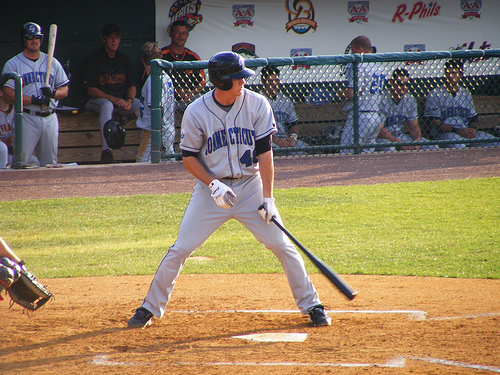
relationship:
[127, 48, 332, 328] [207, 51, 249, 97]
man has head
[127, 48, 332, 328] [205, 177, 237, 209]
man has hand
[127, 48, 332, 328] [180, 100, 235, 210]
man has arm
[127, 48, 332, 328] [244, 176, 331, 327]
man has leg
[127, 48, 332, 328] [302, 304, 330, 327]
man has foot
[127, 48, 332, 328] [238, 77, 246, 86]
man has nose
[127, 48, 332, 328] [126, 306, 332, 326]
man wearing shoes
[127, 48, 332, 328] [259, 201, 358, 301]
man holding bat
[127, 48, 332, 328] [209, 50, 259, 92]
man wearing hat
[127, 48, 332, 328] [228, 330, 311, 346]
man standing near home plate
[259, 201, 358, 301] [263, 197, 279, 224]
bat in left hand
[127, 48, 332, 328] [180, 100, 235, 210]
batter has right arm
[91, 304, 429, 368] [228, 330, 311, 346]
chalk box around home plate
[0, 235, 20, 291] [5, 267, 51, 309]
catcher has glove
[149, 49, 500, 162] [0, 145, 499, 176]
chain link fence at edge of field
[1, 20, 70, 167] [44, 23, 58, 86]
man holding bat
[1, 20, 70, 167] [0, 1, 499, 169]
man in background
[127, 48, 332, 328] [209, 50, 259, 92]
man wearing helmet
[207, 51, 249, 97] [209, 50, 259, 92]
head has helmet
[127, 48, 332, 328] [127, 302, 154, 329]
man has left foot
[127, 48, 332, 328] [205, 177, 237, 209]
man has right hand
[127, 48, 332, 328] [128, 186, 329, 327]
man standing with wide legs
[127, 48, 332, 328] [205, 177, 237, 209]
batter has hand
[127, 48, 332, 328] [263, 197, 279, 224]
batter has hand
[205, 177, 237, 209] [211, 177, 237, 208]
hand has glove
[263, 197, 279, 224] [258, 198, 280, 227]
hand has glove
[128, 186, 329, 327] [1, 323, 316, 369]
batters legs have shadow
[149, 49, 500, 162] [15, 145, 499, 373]
chain-link behind field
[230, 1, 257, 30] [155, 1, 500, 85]
product logo on board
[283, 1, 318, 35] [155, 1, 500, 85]
product logo on board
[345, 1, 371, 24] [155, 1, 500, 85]
product logo on board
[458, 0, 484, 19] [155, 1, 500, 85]
product logo on board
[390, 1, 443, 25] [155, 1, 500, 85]
product logo on board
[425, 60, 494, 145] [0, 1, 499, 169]
player sitting behind fence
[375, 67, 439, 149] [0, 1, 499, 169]
player sitting behind fence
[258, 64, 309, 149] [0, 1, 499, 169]
player sitting behind fence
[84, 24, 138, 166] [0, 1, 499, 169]
player sitting behind fence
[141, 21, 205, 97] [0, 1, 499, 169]
player sitting behind fence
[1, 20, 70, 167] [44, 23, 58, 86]
player holding bat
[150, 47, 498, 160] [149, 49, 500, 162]
railing surrounds chain link fence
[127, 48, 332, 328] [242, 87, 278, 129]
man looking over left shoulder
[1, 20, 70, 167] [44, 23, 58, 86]
man has bat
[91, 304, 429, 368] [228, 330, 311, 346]
marker for home plate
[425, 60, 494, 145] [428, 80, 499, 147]
player wearing uniform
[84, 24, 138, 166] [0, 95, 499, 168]
player sitting on bench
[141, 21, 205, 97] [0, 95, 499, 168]
player sitting on bench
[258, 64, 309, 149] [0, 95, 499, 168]
player sitting on bench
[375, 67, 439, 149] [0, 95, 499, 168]
player sitting on bench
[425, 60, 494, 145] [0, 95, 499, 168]
player sitting on bench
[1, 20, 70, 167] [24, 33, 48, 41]
man wearing sunglasses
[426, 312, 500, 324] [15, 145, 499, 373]
line on ground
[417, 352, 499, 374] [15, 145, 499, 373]
line on ground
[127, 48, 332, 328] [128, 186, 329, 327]
man has legs spread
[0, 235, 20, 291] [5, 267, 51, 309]
catcher has mitt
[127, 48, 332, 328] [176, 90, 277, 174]
man wearing shirt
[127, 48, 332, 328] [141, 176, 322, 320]
man wearing pants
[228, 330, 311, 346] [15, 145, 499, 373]
home plate on field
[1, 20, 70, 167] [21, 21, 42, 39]
man wearing helmet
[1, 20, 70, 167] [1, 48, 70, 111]
man wearing shirt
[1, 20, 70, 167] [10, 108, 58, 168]
man wearing pants